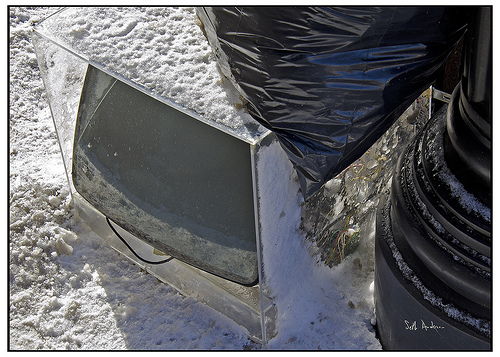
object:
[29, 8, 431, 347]
case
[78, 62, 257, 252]
mirror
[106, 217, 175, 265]
wire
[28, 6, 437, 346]
television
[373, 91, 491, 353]
base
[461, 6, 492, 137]
lamp post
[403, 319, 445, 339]
name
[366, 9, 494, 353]
pole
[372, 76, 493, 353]
tank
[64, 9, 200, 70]
snow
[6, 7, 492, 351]
snow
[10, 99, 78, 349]
rock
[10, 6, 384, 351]
ground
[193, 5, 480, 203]
bag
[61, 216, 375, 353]
shadow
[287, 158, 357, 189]
corner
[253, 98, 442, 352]
triangular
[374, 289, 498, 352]
bottom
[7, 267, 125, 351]
light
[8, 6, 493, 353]
photo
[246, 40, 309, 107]
light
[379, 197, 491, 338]
part